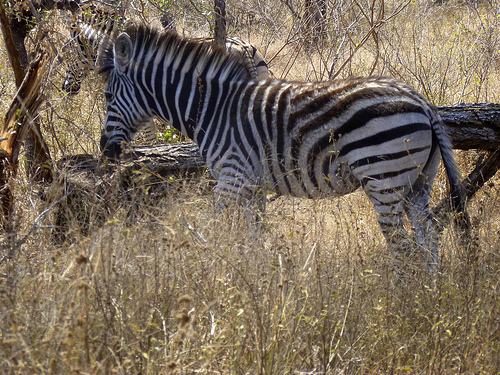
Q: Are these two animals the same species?
A: Yes, all the animals are zebras.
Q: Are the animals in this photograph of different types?
A: No, all the animals are zebras.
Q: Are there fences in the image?
A: No, there are no fences.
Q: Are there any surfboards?
A: No, there are no surfboards.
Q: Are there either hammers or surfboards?
A: No, there are no surfboards or hammers.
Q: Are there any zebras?
A: Yes, there is a zebra.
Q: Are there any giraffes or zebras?
A: Yes, there is a zebra.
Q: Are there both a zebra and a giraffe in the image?
A: No, there is a zebra but no giraffes.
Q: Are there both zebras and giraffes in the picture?
A: No, there is a zebra but no giraffes.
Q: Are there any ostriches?
A: No, there are no ostriches.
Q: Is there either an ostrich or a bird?
A: No, there are no ostriches or birds.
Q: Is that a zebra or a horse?
A: That is a zebra.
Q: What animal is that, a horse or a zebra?
A: That is a zebra.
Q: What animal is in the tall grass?
A: The zebra is in the grass.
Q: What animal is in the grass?
A: The zebra is in the grass.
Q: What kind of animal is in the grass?
A: The animal is a zebra.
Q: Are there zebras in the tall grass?
A: Yes, there is a zebra in the grass.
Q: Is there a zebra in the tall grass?
A: Yes, there is a zebra in the grass.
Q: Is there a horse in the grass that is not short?
A: No, there is a zebra in the grass.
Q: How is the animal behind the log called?
A: The animal is a zebra.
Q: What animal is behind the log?
A: The animal is a zebra.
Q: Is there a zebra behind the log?
A: Yes, there is a zebra behind the log.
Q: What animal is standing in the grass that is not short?
A: The zebra is standing in the grass.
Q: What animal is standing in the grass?
A: The zebra is standing in the grass.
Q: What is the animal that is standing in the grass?
A: The animal is a zebra.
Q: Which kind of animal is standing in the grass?
A: The animal is a zebra.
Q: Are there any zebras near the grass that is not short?
A: Yes, there is a zebra near the grass.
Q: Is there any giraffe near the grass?
A: No, there is a zebra near the grass.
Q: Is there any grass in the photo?
A: Yes, there is grass.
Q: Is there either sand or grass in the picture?
A: Yes, there is grass.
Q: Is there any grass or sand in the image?
A: Yes, there is grass.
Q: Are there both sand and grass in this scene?
A: No, there is grass but no sand.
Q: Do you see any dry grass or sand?
A: Yes, there is dry grass.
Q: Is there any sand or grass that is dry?
A: Yes, the grass is dry.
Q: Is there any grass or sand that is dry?
A: Yes, the grass is dry.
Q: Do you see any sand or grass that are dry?
A: Yes, the grass is dry.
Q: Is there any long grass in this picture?
A: Yes, there is long grass.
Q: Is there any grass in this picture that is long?
A: Yes, there is grass that is long.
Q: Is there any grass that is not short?
A: Yes, there is long grass.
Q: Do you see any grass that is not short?
A: Yes, there is long grass.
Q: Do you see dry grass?
A: Yes, there is dry grass.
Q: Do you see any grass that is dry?
A: Yes, there is grass that is dry.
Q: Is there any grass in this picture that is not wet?
A: Yes, there is dry grass.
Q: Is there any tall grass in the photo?
A: Yes, there is tall grass.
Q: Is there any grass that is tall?
A: Yes, there is grass that is tall.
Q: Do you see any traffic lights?
A: No, there are no traffic lights.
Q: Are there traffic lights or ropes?
A: No, there are no traffic lights or ropes.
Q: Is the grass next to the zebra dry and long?
A: Yes, the grass is dry and long.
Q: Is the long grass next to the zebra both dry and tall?
A: Yes, the grass is dry and tall.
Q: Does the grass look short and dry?
A: No, the grass is dry but tall.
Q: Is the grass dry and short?
A: No, the grass is dry but tall.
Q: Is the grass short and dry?
A: No, the grass is dry but tall.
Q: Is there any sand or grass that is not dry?
A: No, there is grass but it is dry.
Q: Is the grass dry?
A: Yes, the grass is dry.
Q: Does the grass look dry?
A: Yes, the grass is dry.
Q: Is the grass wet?
A: No, the grass is dry.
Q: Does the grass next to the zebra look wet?
A: No, the grass is dry.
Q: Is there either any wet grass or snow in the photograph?
A: No, there is grass but it is dry.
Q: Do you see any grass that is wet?
A: No, there is grass but it is dry.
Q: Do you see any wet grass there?
A: No, there is grass but it is dry.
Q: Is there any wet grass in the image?
A: No, there is grass but it is dry.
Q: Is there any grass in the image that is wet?
A: No, there is grass but it is dry.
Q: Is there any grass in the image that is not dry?
A: No, there is grass but it is dry.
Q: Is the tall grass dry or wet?
A: The grass is dry.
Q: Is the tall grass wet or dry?
A: The grass is dry.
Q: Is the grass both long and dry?
A: Yes, the grass is long and dry.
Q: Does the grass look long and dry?
A: Yes, the grass is long and dry.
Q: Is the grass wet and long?
A: No, the grass is long but dry.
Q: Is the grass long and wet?
A: No, the grass is long but dry.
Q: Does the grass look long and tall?
A: Yes, the grass is long and tall.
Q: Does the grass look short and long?
A: No, the grass is long but tall.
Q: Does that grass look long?
A: Yes, the grass is long.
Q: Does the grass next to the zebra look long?
A: Yes, the grass is long.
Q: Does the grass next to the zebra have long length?
A: Yes, the grass is long.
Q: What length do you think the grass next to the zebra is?
A: The grass is long.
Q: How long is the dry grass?
A: The grass is long.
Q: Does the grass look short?
A: No, the grass is long.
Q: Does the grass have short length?
A: No, the grass is long.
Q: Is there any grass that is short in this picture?
A: No, there is grass but it is long.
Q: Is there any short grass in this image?
A: No, there is grass but it is long.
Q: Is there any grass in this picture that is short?
A: No, there is grass but it is long.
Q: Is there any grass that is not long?
A: No, there is grass but it is long.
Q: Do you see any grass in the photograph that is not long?
A: No, there is grass but it is long.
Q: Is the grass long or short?
A: The grass is long.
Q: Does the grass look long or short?
A: The grass is long.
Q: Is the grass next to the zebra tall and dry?
A: Yes, the grass is tall and dry.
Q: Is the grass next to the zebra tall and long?
A: Yes, the grass is tall and long.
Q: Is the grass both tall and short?
A: No, the grass is tall but long.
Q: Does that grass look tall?
A: Yes, the grass is tall.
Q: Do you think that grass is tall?
A: Yes, the grass is tall.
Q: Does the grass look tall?
A: Yes, the grass is tall.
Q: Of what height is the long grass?
A: The grass is tall.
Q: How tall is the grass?
A: The grass is tall.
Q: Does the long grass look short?
A: No, the grass is tall.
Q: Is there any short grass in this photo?
A: No, there is grass but it is tall.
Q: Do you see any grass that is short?
A: No, there is grass but it is tall.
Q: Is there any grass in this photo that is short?
A: No, there is grass but it is tall.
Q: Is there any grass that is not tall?
A: No, there is grass but it is tall.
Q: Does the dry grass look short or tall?
A: The grass is tall.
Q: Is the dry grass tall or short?
A: The grass is tall.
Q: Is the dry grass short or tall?
A: The grass is tall.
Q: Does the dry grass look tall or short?
A: The grass is tall.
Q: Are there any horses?
A: No, there are no horses.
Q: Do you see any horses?
A: No, there are no horses.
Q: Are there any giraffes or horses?
A: No, there are no horses or giraffes.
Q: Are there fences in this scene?
A: No, there are no fences.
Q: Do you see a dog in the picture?
A: No, there are no dogs.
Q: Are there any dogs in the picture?
A: No, there are no dogs.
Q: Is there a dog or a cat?
A: No, there are no dogs or cats.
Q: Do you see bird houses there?
A: No, there are no bird houses.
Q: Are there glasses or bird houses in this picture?
A: No, there are no bird houses or glasses.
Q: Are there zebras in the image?
A: Yes, there is a zebra.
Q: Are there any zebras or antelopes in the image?
A: Yes, there is a zebra.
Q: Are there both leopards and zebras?
A: No, there is a zebra but no leopards.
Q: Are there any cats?
A: No, there are no cats.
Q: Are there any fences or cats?
A: No, there are no cats or fences.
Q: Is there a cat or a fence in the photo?
A: No, there are no cats or fences.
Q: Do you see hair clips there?
A: No, there are no hair clips.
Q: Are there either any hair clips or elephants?
A: No, there are no hair clips or elephants.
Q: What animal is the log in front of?
A: The log is in front of the zebra.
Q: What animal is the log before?
A: The log is in front of the zebra.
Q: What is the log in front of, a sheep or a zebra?
A: The log is in front of a zebra.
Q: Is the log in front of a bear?
A: No, the log is in front of the zebra.